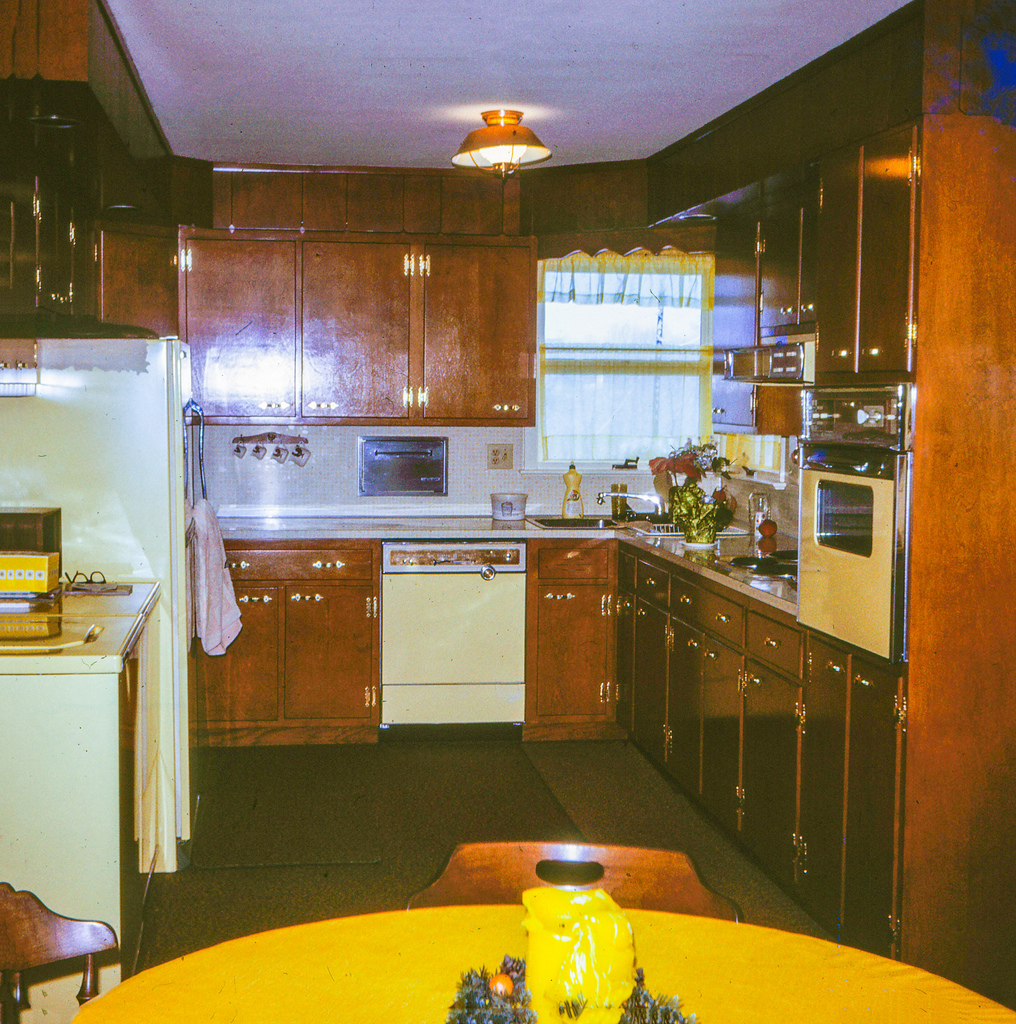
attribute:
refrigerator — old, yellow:
[6, 347, 201, 870]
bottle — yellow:
[562, 462, 583, 514]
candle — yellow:
[519, 874, 648, 1014]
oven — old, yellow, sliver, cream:
[796, 385, 909, 659]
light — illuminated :
[451, 104, 546, 186]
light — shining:
[185, 327, 379, 419]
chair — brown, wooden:
[409, 832, 738, 920]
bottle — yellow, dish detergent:
[563, 456, 587, 524]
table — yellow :
[243, 889, 427, 1022]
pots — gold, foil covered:
[642, 486, 741, 569]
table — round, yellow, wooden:
[67, 898, 1014, 1019]